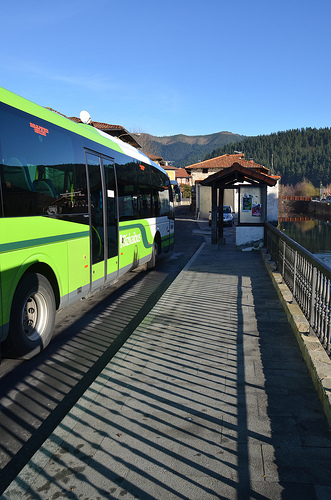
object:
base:
[259, 246, 331, 433]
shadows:
[147, 204, 271, 280]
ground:
[0, 203, 330, 500]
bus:
[0, 83, 182, 362]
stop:
[198, 161, 281, 252]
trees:
[323, 155, 331, 187]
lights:
[0, 103, 99, 168]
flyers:
[241, 194, 254, 214]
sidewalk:
[0, 239, 331, 499]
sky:
[0, 0, 331, 138]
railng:
[263, 221, 331, 360]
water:
[278, 217, 331, 268]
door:
[82, 146, 120, 290]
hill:
[131, 124, 330, 196]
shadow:
[0, 265, 285, 497]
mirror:
[173, 184, 182, 203]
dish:
[79, 109, 91, 125]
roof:
[184, 152, 271, 177]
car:
[208, 205, 236, 228]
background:
[0, 0, 331, 183]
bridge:
[0, 195, 331, 500]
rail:
[264, 220, 331, 282]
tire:
[4, 271, 57, 362]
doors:
[165, 185, 176, 255]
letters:
[44, 128, 49, 133]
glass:
[0, 100, 76, 218]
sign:
[139, 164, 146, 171]